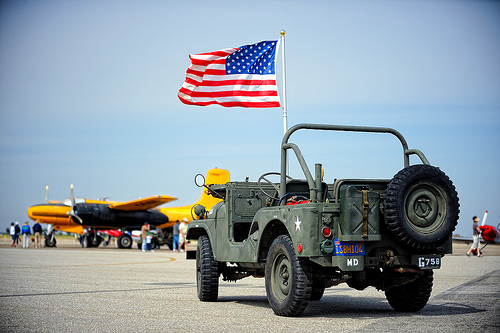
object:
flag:
[177, 28, 290, 179]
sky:
[0, 0, 500, 211]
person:
[466, 215, 484, 257]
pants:
[471, 235, 481, 251]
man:
[178, 217, 189, 255]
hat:
[182, 217, 188, 222]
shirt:
[179, 222, 189, 235]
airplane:
[471, 210, 500, 256]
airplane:
[27, 166, 231, 246]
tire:
[382, 163, 460, 252]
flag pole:
[281, 36, 290, 180]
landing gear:
[82, 226, 134, 248]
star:
[294, 215, 302, 232]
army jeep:
[184, 122, 461, 316]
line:
[0, 256, 177, 268]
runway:
[0, 236, 500, 333]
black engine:
[71, 202, 170, 229]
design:
[294, 215, 302, 231]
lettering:
[335, 245, 363, 254]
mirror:
[193, 173, 225, 200]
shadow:
[214, 287, 489, 319]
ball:
[280, 29, 287, 36]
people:
[21, 221, 32, 249]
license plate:
[333, 238, 366, 256]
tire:
[264, 234, 313, 316]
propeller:
[65, 183, 82, 232]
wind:
[0, 0, 500, 332]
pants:
[178, 233, 188, 243]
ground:
[0, 245, 500, 333]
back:
[282, 122, 460, 317]